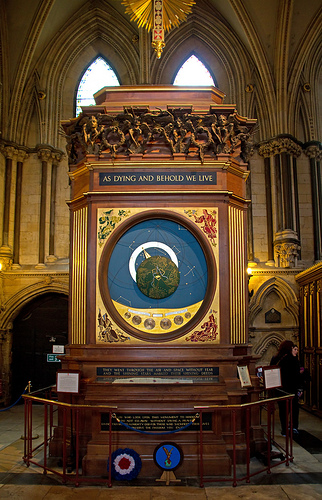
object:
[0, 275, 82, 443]
doorway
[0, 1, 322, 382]
wall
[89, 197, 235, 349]
device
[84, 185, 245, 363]
side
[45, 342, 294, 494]
side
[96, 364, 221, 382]
writing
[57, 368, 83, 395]
sign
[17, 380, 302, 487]
barrier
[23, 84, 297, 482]
tower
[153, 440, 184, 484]
picture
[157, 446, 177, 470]
eagle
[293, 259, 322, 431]
case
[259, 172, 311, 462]
side